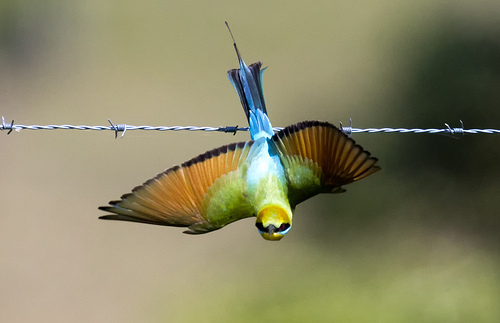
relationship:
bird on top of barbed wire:
[148, 51, 371, 233] [0, 122, 498, 136]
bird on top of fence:
[85, 26, 385, 254] [20, 101, 197, 138]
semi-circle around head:
[248, 202, 288, 235] [242, 201, 296, 237]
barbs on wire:
[97, 118, 132, 138] [7, 112, 497, 142]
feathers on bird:
[148, 160, 210, 210] [81, 46, 379, 243]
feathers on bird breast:
[250, 134, 280, 167] [250, 140, 279, 176]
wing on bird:
[96, 150, 235, 244] [100, 45, 407, 239]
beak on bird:
[258, 226, 278, 237] [83, 14, 387, 254]